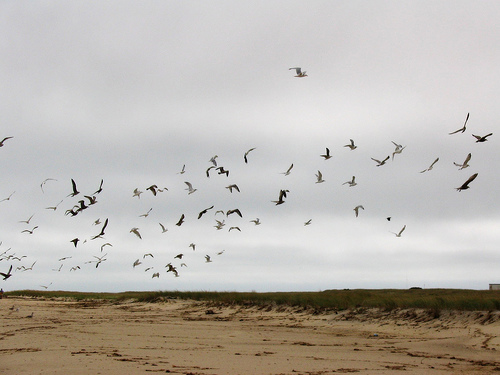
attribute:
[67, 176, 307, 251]
birds — flying, in sky, abundant, flying over beach, in photo, at beach, close to beach, in a flock, mid air, over beach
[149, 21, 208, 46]
sky — gray, cloudy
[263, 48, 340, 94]
bird — flying higher, mid air, light colored, against sky, dark, above others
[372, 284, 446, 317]
grass — in background, near beach, green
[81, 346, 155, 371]
footprints — in sand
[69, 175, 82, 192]
wing — pointing up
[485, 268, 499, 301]
building — distant, in distance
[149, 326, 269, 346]
beach — brown, under sky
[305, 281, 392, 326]
hill — small